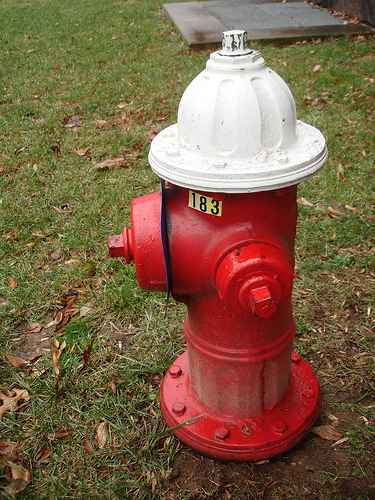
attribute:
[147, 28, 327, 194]
top — white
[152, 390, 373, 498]
dirt — dark, brown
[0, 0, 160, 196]
grass — brown, short, green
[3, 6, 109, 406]
grass — short, green, brown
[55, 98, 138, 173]
grass — green, short, brown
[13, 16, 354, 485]
grass — green, brown, short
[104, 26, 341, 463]
hydrant — red, white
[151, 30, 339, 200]
top part — white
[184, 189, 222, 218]
numbers — black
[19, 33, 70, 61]
grass — brown, short, green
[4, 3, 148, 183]
grass — green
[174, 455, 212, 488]
dirt — brown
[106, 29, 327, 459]
fire hydrant — red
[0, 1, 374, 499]
grass — brown, short, green, area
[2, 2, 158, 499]
grass — short, green, brown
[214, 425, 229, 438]
red bolt — base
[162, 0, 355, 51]
slab — concrete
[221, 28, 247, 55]
bolt — large, white